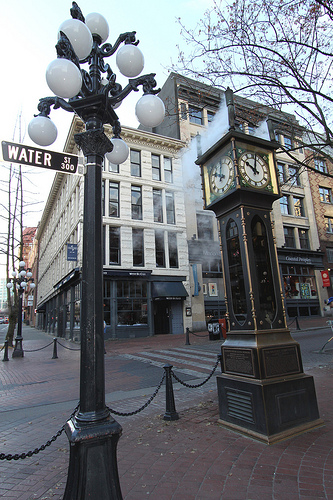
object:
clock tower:
[202, 133, 277, 204]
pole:
[77, 159, 112, 414]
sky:
[0, 0, 30, 74]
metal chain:
[107, 380, 178, 424]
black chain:
[116, 384, 170, 416]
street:
[3, 354, 23, 417]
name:
[285, 252, 312, 264]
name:
[126, 267, 147, 277]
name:
[165, 293, 184, 301]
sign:
[0, 142, 86, 175]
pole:
[76, 146, 112, 406]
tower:
[209, 112, 284, 261]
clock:
[237, 150, 267, 186]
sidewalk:
[226, 449, 268, 495]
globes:
[134, 83, 170, 135]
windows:
[131, 224, 144, 268]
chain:
[124, 389, 158, 408]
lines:
[240, 445, 273, 498]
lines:
[191, 431, 241, 498]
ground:
[0, 321, 332, 498]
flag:
[67, 241, 78, 260]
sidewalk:
[136, 425, 172, 481]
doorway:
[149, 331, 186, 349]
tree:
[4, 167, 24, 366]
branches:
[33, 118, 190, 341]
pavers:
[49, 367, 72, 384]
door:
[151, 299, 172, 337]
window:
[128, 145, 142, 177]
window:
[149, 150, 161, 181]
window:
[163, 153, 174, 183]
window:
[108, 178, 119, 218]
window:
[130, 182, 143, 222]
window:
[151, 186, 163, 224]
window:
[166, 189, 174, 220]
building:
[37, 112, 191, 352]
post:
[75, 128, 111, 413]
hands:
[213, 163, 227, 181]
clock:
[202, 145, 232, 197]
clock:
[235, 137, 276, 189]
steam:
[177, 111, 210, 194]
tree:
[177, 1, 330, 145]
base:
[216, 372, 317, 449]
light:
[26, 102, 66, 148]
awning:
[153, 281, 189, 298]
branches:
[176, 74, 324, 337]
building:
[39, 113, 189, 339]